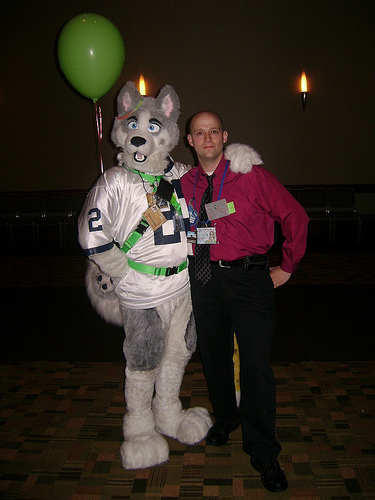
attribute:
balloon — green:
[54, 10, 129, 110]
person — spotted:
[77, 82, 215, 476]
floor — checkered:
[3, 257, 374, 499]